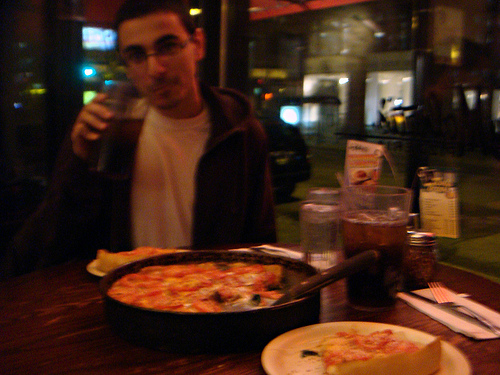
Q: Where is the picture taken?
A: A restaurant.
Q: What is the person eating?
A: Pizza.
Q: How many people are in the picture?
A: One.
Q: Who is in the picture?
A: A man.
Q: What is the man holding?
A: A glass.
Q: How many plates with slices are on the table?
A: Two.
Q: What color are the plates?
A: White.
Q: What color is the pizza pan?
A: Black.